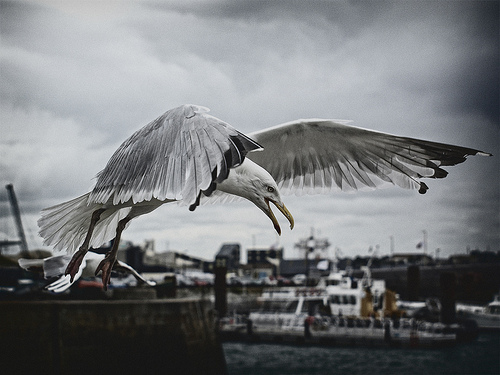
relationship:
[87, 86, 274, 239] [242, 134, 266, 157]
feathers on tip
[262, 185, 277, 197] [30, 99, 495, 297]
eye on seagull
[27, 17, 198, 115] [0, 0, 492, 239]
clouds in sky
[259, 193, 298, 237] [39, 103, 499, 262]
beak on bird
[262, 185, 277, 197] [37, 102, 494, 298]
eye of bird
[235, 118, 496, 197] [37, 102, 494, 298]
left wing of bird